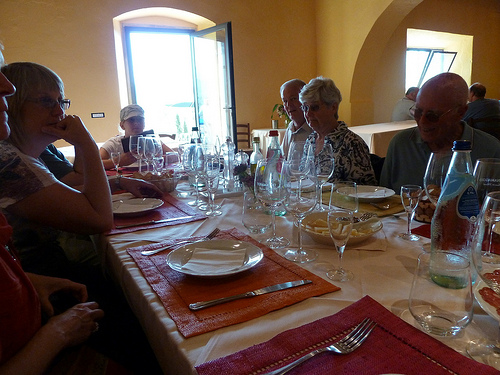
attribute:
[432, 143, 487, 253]
bottle — empty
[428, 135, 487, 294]
bottle — empty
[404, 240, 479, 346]
glass — empty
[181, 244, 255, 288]
napkin — red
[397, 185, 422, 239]
glass — short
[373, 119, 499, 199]
shirt — blue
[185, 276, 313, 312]
utensil — metal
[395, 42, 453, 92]
window — opened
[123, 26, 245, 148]
window — opened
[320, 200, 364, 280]
glass — empty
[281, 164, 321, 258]
glass — empty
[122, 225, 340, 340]
mat — red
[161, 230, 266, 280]
plate — white